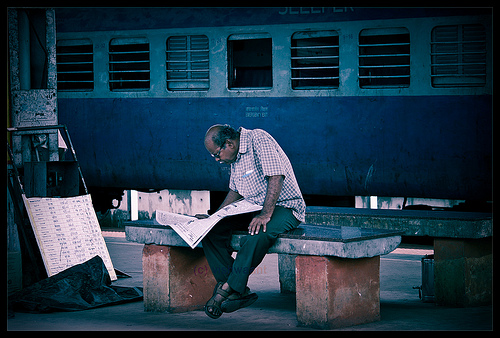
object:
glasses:
[210, 142, 225, 158]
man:
[203, 124, 307, 320]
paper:
[156, 196, 265, 249]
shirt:
[229, 127, 307, 224]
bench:
[125, 224, 404, 328]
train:
[59, 0, 500, 205]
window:
[227, 33, 274, 91]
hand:
[247, 214, 271, 236]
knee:
[245, 224, 278, 242]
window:
[291, 31, 341, 89]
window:
[360, 28, 408, 89]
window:
[431, 24, 486, 89]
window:
[166, 35, 209, 92]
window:
[110, 40, 148, 91]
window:
[56, 38, 93, 91]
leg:
[294, 256, 382, 329]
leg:
[143, 244, 204, 313]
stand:
[5, 126, 119, 290]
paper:
[22, 194, 117, 282]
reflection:
[331, 226, 366, 241]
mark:
[243, 106, 270, 118]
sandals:
[220, 289, 262, 313]